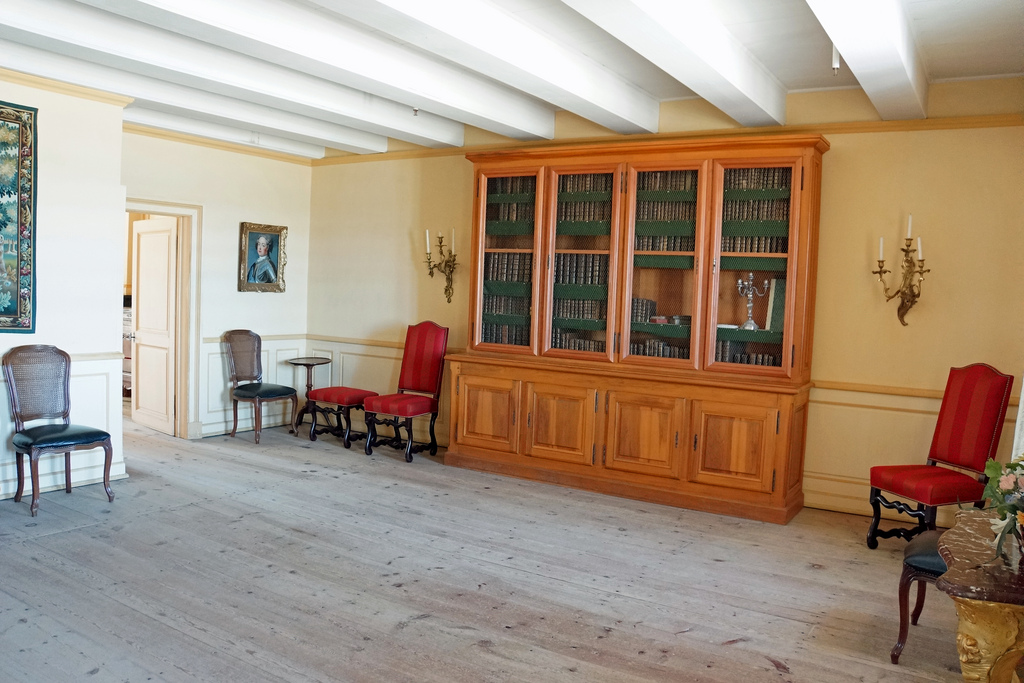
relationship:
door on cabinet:
[452, 377, 516, 454] [464, 130, 812, 390]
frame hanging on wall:
[238, 222, 287, 292] [198, 158, 333, 420]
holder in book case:
[728, 266, 772, 331] [460, 148, 824, 382]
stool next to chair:
[301, 309, 442, 459] [375, 318, 451, 450]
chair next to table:
[207, 321, 326, 445] [289, 357, 339, 403]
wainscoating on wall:
[307, 84, 1020, 518] [298, 158, 992, 440]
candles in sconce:
[873, 212, 927, 261] [867, 241, 929, 322]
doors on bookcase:
[466, 146, 803, 378] [437, 130, 829, 523]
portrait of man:
[235, 219, 289, 293] [255, 238, 277, 273]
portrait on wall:
[235, 219, 289, 293] [188, 147, 309, 418]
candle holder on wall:
[867, 209, 932, 327] [307, 167, 982, 373]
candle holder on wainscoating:
[418, 221, 463, 301] [307, 117, 1024, 518]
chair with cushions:
[860, 360, 1016, 548] [867, 360, 1016, 506]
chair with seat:
[1, 342, 115, 511] [11, 428, 124, 455]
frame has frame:
[238, 222, 287, 292] [237, 225, 300, 297]